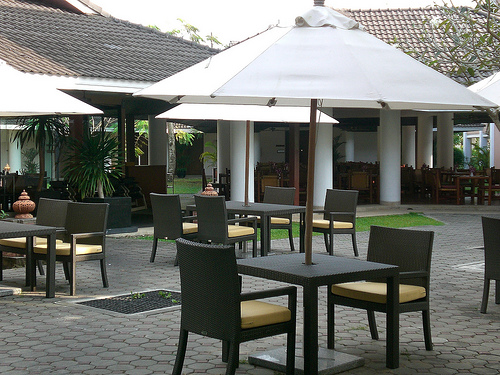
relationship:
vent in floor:
[69, 283, 182, 317] [0, 206, 498, 374]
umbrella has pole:
[131, 7, 499, 375] [300, 98, 323, 269]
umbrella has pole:
[155, 106, 340, 260] [238, 120, 255, 205]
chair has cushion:
[165, 237, 299, 374] [238, 295, 290, 329]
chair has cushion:
[325, 225, 433, 368] [331, 280, 425, 304]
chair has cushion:
[41, 201, 111, 299] [32, 242, 105, 257]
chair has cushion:
[0, 197, 72, 283] [0, 237, 61, 248]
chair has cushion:
[144, 193, 194, 266] [181, 221, 198, 235]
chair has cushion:
[197, 196, 257, 254] [225, 223, 255, 237]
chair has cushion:
[244, 188, 295, 255] [270, 216, 290, 225]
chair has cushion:
[303, 187, 360, 258] [311, 218, 354, 228]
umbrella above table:
[131, 7, 499, 375] [228, 252, 400, 367]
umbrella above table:
[155, 106, 340, 260] [187, 197, 311, 261]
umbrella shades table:
[131, 7, 499, 375] [228, 252, 400, 367]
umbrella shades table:
[155, 106, 340, 260] [187, 197, 311, 261]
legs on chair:
[326, 296, 433, 370] [325, 225, 433, 368]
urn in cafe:
[197, 185, 220, 214] [0, 2, 497, 372]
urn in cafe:
[11, 190, 34, 227] [0, 2, 497, 372]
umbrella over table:
[126, 0, 496, 261] [2, 220, 55, 295]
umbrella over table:
[144, 87, 338, 260] [183, 197, 305, 249]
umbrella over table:
[0, 62, 104, 114] [228, 252, 400, 367]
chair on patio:
[303, 187, 360, 258] [7, 197, 493, 371]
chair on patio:
[188, 191, 265, 260] [7, 197, 493, 371]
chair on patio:
[139, 183, 204, 266] [7, 197, 493, 371]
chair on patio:
[325, 225, 433, 368] [7, 197, 493, 371]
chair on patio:
[165, 237, 299, 374] [7, 197, 493, 371]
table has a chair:
[228, 252, 400, 367] [170, 233, 297, 369]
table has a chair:
[228, 252, 400, 367] [326, 223, 436, 357]